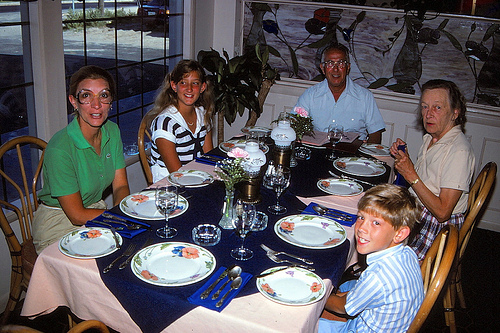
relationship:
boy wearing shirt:
[314, 184, 424, 332] [343, 241, 425, 333]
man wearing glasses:
[294, 45, 385, 146] [322, 57, 348, 69]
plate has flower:
[132, 241, 216, 287] [171, 245, 198, 260]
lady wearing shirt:
[33, 64, 131, 257] [38, 116, 127, 207]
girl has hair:
[142, 59, 213, 188] [142, 57, 218, 134]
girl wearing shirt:
[142, 59, 213, 188] [149, 101, 214, 167]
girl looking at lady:
[142, 59, 213, 188] [33, 64, 131, 257]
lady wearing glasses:
[33, 64, 131, 257] [73, 88, 114, 104]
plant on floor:
[191, 41, 281, 145] [1, 225, 497, 332]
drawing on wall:
[241, 1, 500, 109] [212, 0, 499, 231]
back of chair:
[2, 135, 47, 246] [1, 135, 49, 323]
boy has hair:
[314, 184, 424, 332] [357, 184, 423, 231]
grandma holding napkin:
[390, 77, 475, 267] [390, 142, 408, 160]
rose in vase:
[226, 147, 249, 159] [216, 178, 238, 228]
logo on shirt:
[105, 152, 114, 161] [38, 116, 127, 207]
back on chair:
[2, 135, 47, 246] [1, 135, 49, 323]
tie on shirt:
[188, 130, 206, 159] [149, 101, 214, 167]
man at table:
[294, 45, 385, 146] [40, 126, 397, 331]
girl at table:
[142, 59, 213, 188] [40, 126, 397, 331]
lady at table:
[33, 64, 131, 257] [40, 126, 397, 331]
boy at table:
[314, 184, 424, 332] [40, 126, 397, 331]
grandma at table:
[390, 77, 475, 267] [40, 126, 397, 331]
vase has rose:
[216, 178, 238, 228] [226, 147, 249, 159]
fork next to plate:
[265, 250, 315, 273] [259, 267, 327, 305]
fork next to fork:
[261, 245, 315, 269] [265, 250, 315, 273]